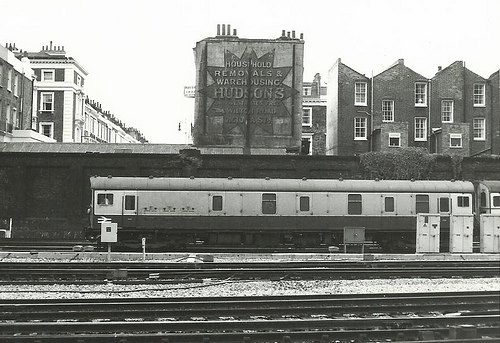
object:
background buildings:
[0, 24, 500, 256]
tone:
[85, 163, 482, 196]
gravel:
[0, 280, 500, 300]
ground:
[0, 240, 500, 343]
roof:
[90, 180, 475, 193]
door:
[123, 195, 137, 227]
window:
[96, 193, 114, 206]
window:
[212, 195, 224, 214]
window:
[415, 194, 431, 214]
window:
[299, 195, 311, 213]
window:
[348, 194, 363, 216]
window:
[385, 197, 395, 212]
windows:
[457, 196, 471, 208]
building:
[331, 60, 497, 157]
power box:
[415, 213, 441, 254]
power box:
[449, 214, 476, 253]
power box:
[480, 206, 500, 254]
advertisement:
[192, 34, 303, 149]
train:
[86, 175, 499, 249]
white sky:
[0, 0, 500, 150]